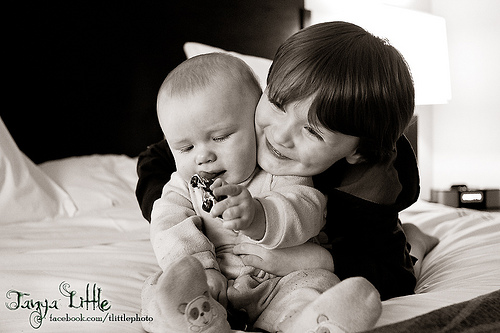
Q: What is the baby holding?
A: Toy car.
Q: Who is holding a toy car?
A: The baby.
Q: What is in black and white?
A: The photograph.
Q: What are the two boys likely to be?
A: Brothers.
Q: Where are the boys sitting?
A: On the bed.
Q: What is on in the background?
A: A lamp.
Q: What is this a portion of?
A: A pillow.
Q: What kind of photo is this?
A: Black and white.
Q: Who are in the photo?
A: Two children.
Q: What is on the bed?
A: Two kids.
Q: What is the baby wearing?
A: Pajamas.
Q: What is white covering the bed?
A: Sheets.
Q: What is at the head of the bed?
A: A headboard.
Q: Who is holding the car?
A: The baby.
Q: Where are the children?
A: In bed.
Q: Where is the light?
A: Behind the children.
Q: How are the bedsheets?
A: They are white.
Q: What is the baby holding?
A: A car.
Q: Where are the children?
A: On the bed.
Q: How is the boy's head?
A: With hair.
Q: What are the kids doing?
A: Hugging.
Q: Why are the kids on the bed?
A: Laying down.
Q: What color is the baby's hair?
A: Light brown.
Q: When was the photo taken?
A: Day time.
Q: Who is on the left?
A: A boy.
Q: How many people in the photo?
A: Two.